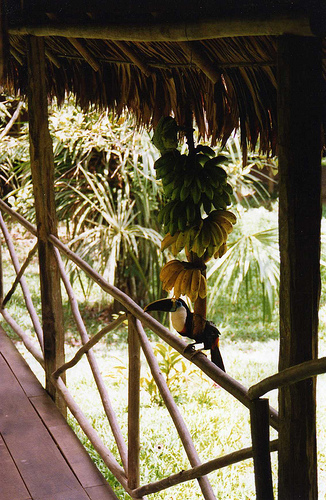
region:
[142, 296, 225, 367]
tropical bird sitting on the rail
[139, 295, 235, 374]
colorful toucan with many colors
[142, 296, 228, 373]
toucan sitting on the bananas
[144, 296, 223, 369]
toucan resting under the bananas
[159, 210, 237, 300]
bunches of yellow bananas hanging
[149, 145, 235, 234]
bunches of green bananas hanging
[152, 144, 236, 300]
bunches of bananas growing on a tree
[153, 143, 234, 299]
bunches of bananas over the bird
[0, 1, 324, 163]
leaves used for the roof of the hut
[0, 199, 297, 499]
wooden rails for the hut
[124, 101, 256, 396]
This is a banana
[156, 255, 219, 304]
A bunch of banana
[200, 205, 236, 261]
A bunch of banana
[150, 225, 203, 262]
A bunch of banana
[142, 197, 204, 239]
A bunch of banana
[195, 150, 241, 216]
A bunch of banana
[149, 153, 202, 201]
A bunch of banana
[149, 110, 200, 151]
A bunch of banana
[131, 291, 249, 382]
This is a horn bill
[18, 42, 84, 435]
This is a pole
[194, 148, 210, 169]
part of a stalk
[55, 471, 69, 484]
part of a floor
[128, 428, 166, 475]
part of a stick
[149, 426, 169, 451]
part of a plant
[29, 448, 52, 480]
part of a floor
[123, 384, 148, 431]
part of a stick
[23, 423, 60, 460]
part of a floor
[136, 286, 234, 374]
Tucan on a wooden fence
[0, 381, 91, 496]
wooden deck planks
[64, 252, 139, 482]
wooden railing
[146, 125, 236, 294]
bananas hanging of the roof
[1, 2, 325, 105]
thatched roofing made from palm leaves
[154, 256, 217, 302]
yellow bunch of bananas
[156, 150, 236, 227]
green bunches of bananas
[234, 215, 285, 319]
a small palm tree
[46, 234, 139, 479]
an X in the wooden railing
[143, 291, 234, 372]
a tukan resting on the railing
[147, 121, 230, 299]
Bunch of bananas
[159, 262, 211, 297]
Yellow color banana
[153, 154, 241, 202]
Green color banana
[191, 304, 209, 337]
Stem of the banana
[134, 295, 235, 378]
A bird sitting near the banana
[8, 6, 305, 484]
A tent with wooden floor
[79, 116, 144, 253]
Plants near the tent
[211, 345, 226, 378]
Tail of the bird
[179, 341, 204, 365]
Legs of the bird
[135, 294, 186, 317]
Head of the bird